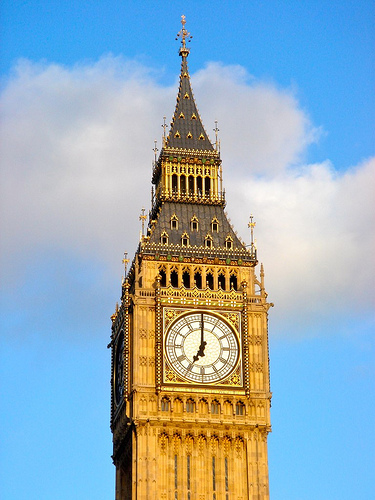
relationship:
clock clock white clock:
[155, 297, 249, 398] [156, 306, 241, 388]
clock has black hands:
[155, 297, 249, 398] [198, 313, 207, 350]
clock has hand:
[155, 297, 249, 398] [190, 341, 207, 362]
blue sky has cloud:
[5, 4, 365, 479] [0, 53, 373, 339]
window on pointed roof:
[209, 213, 222, 235] [150, 14, 228, 209]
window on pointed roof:
[190, 213, 199, 230] [150, 14, 228, 209]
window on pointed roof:
[166, 212, 178, 229] [150, 14, 228, 209]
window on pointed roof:
[156, 229, 170, 242] [150, 14, 228, 209]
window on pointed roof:
[224, 234, 234, 246] [150, 14, 228, 209]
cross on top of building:
[168, 13, 204, 51] [106, 13, 275, 499]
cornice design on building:
[131, 256, 261, 293] [106, 13, 275, 499]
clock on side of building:
[112, 326, 128, 405] [106, 13, 275, 499]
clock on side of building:
[155, 297, 249, 398] [106, 13, 275, 499]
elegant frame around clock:
[153, 289, 252, 399] [155, 297, 249, 398]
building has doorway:
[106, 13, 275, 499] [228, 272, 238, 291]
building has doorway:
[106, 13, 275, 499] [217, 272, 225, 293]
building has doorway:
[106, 13, 275, 499] [206, 271, 212, 287]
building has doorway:
[106, 13, 275, 499] [193, 268, 203, 290]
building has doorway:
[106, 13, 275, 499] [168, 267, 179, 288]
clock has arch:
[155, 300, 248, 395] [234, 399, 247, 416]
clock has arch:
[155, 300, 248, 395] [223, 398, 235, 417]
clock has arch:
[155, 300, 248, 395] [210, 393, 221, 413]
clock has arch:
[155, 300, 248, 395] [186, 394, 196, 412]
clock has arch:
[155, 300, 248, 395] [158, 392, 172, 411]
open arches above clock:
[154, 265, 251, 290] [155, 297, 249, 398]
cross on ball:
[168, 13, 204, 51] [179, 46, 189, 58]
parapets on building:
[159, 159, 232, 196] [106, 13, 275, 499]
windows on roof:
[156, 210, 239, 249] [136, 199, 251, 252]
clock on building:
[155, 297, 249, 398] [106, 13, 275, 499]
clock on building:
[112, 326, 128, 407] [106, 13, 275, 499]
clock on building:
[155, 297, 249, 398] [79, 13, 296, 499]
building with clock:
[79, 13, 296, 499] [163, 305, 245, 383]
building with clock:
[106, 13, 275, 499] [159, 305, 248, 389]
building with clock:
[106, 13, 275, 499] [163, 305, 245, 383]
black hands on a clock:
[184, 313, 209, 374] [163, 305, 245, 383]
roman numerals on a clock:
[167, 317, 243, 381] [155, 297, 249, 398]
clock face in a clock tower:
[164, 311, 237, 390] [107, 12, 276, 498]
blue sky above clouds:
[5, 4, 365, 479] [233, 64, 363, 216]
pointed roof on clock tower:
[150, 19, 232, 152] [107, 12, 276, 498]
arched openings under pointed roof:
[161, 169, 221, 206] [158, 10, 220, 155]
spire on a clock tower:
[153, 15, 237, 153] [107, 12, 276, 498]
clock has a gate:
[155, 297, 249, 398] [153, 265, 251, 301]